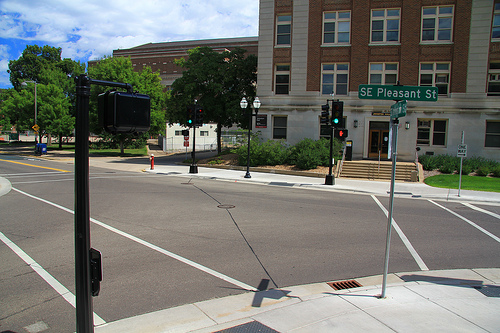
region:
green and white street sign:
[351, 74, 443, 306]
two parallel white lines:
[375, 188, 497, 268]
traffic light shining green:
[324, 96, 349, 182]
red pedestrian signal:
[336, 126, 350, 141]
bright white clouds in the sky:
[2, 1, 265, 80]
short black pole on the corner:
[49, 73, 154, 330]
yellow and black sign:
[32, 122, 40, 132]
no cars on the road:
[0, 143, 499, 328]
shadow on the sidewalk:
[399, 265, 499, 307]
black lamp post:
[232, 90, 267, 176]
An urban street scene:
[3, 2, 495, 330]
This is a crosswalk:
[1, 178, 271, 325]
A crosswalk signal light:
[69, 69, 154, 331]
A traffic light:
[314, 94, 348, 186]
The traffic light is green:
[329, 115, 344, 125]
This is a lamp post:
[237, 94, 264, 179]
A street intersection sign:
[357, 77, 441, 299]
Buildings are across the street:
[109, 0, 498, 183]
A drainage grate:
[326, 272, 363, 294]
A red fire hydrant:
[147, 149, 159, 171]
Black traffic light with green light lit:
[319, 97, 344, 185]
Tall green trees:
[2, 43, 163, 157]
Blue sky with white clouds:
[10, 5, 255, 85]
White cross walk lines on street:
[3, 179, 257, 325]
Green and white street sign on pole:
[356, 82, 424, 298]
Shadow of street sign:
[218, 276, 379, 306]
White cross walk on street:
[368, 191, 493, 270]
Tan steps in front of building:
[333, 157, 426, 185]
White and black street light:
[237, 94, 261, 178]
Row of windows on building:
[268, 6, 457, 47]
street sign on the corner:
[342, 74, 433, 311]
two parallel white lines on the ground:
[1, 185, 263, 332]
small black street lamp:
[225, 90, 271, 181]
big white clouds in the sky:
[0, 1, 260, 73]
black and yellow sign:
[30, 121, 40, 134]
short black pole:
[47, 61, 212, 331]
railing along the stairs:
[369, 143, 386, 178]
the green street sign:
[358, 84, 437, 101]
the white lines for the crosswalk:
[0, 177, 261, 329]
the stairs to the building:
[339, 150, 421, 185]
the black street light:
[237, 93, 262, 185]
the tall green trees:
[3, 38, 253, 163]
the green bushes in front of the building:
[231, 130, 341, 171]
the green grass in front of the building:
[423, 170, 498, 192]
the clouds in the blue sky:
[1, 1, 260, 84]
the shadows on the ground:
[222, 255, 499, 306]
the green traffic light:
[187, 117, 194, 124]